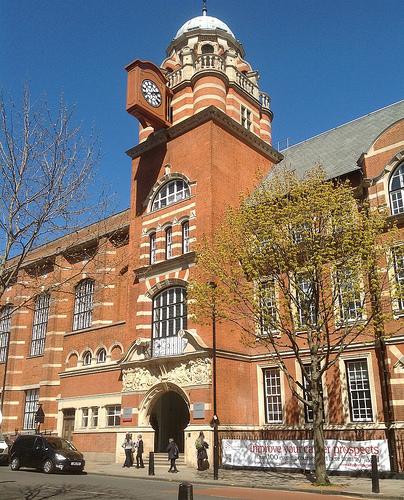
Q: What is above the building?
A: The sky.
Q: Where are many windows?
A: On a building.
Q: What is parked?
A: A car.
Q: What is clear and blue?
A: The sky.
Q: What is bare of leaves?
A: Tree on left.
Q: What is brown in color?
A: The building.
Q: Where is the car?
A: Next to the sidewalk.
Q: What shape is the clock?
A: Round.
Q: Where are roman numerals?
A: On the clock.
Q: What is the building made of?
A: Brick.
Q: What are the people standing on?
A: Sidewalk.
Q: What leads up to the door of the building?
A: Steps.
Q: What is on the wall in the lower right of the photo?
A: Banner.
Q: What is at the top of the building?
A: Dome.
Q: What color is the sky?
A: Blue.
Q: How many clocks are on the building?
A: 1.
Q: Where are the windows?
A: On the building.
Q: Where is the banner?
A: On the building.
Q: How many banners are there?
A: 1.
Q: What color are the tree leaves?
A: Green.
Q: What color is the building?
A: Brown and tan.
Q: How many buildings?
A: 1.